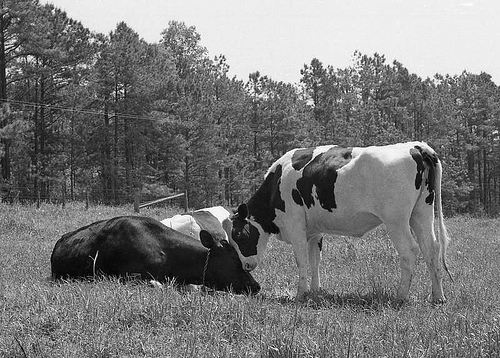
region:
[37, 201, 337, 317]
the cow is resting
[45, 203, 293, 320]
cow touching other cow's head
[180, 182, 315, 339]
cow touching other cow's head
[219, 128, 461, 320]
white cow with black spots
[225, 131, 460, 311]
cow standing on grass field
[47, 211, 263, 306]
black cow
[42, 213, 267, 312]
cow laying on the grass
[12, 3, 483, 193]
forest of trees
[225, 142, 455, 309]
black and white cow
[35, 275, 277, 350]
lush grassy field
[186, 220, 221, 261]
ear of a black cow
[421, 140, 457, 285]
tail of a cow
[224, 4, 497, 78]
clear bright cloudless sky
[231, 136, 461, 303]
Black and white spotted cow.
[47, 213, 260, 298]
Black cow sitting down.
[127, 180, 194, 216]
Gate in the background.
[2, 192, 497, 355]
Grass covering the ground.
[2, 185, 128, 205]
Fence in the background.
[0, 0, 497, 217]
Trees in the background.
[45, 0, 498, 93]
White sky in the background.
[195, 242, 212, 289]
Rope around cows neck.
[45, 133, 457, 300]
Three cows in the pasture.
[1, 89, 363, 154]
Power lines in the background.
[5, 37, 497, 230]
tall trees behind grassy field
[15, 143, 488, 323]
cows in grassy field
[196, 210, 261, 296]
two cows with heads together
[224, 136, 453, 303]
brown and white cow with head down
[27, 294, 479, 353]
grass and weeds in field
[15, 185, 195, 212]
wood posts and wire fencing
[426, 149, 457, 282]
cow tail hanging straight down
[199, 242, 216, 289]
rope around cow's neck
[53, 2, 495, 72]
clear sky above treetops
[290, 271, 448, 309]
four cow hooves standing in grass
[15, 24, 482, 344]
picture is black and white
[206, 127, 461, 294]
the cow is black and white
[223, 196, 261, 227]
the ear is black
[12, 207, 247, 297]
the cow is laying in the grass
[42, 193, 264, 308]
the cow is black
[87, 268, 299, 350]
the grass is tall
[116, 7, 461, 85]
the sky is overcast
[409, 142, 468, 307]
the tail is long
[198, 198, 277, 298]
the cows heads are touching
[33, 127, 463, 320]
3 cows in the grass